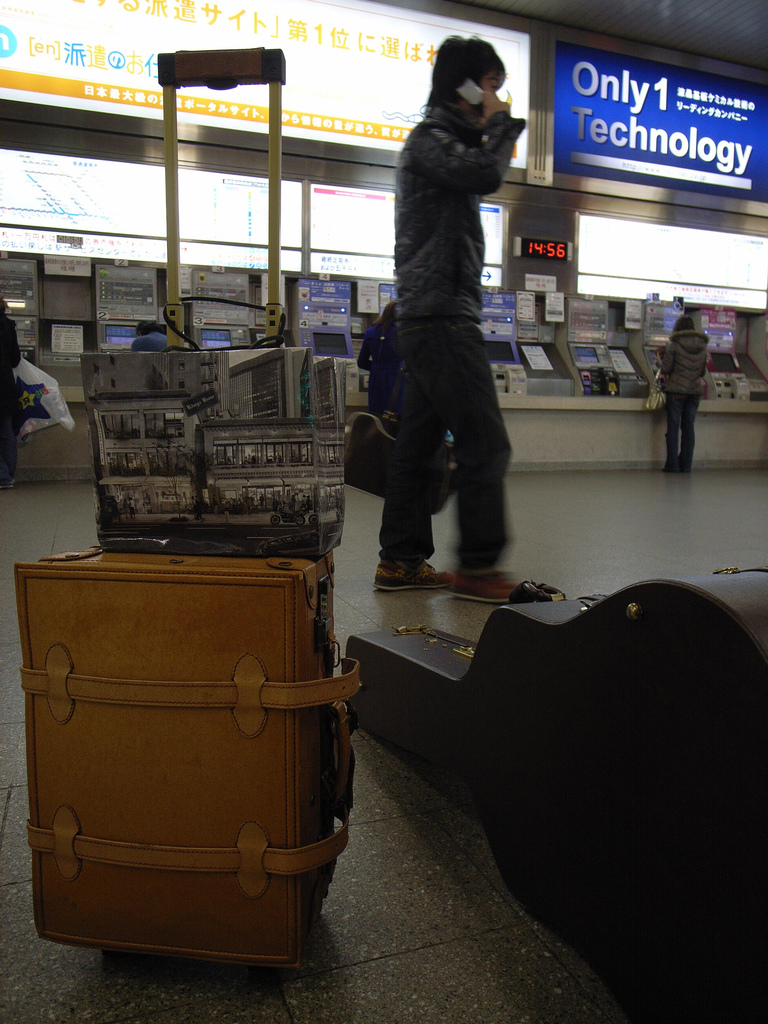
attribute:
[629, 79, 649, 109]
letter — white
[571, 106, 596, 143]
letter — white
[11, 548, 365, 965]
suitcase — brown, leather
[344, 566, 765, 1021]
guitar case — black, large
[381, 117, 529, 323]
coat — black, leather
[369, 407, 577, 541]
jeans — blue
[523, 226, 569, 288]
clock — black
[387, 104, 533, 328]
coat — grey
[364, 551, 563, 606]
shoes — grey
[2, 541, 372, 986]
suitcase — brown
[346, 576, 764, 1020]
case — black, guitar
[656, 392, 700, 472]
jeans — blue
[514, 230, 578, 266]
sign — it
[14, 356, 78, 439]
bag — big, white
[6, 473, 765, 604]
floor — grey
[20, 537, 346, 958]
suitcase — brown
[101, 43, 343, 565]
carrier — luggage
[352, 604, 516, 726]
case — guitar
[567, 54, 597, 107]
letter — white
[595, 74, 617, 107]
letter — white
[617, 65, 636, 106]
letter — white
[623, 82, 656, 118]
letter — white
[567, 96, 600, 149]
letter — white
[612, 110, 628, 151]
letter — white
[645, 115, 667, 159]
letter — white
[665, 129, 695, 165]
letter — white